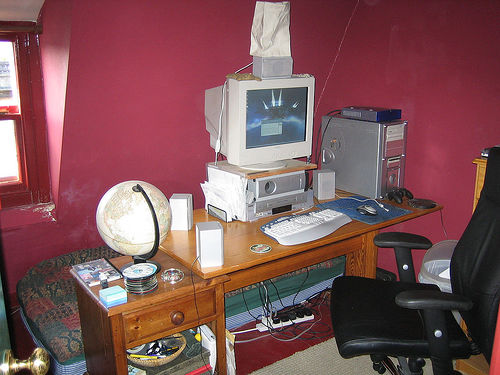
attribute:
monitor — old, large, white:
[229, 76, 315, 164]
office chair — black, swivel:
[327, 146, 484, 373]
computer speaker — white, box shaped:
[194, 220, 224, 270]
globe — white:
[94, 180, 172, 254]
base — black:
[123, 253, 160, 272]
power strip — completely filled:
[256, 303, 316, 329]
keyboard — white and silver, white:
[263, 205, 353, 247]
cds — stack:
[123, 261, 161, 294]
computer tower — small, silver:
[317, 109, 408, 197]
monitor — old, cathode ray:
[203, 70, 317, 174]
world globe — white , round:
[92, 179, 172, 261]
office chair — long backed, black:
[321, 146, 497, 367]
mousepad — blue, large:
[311, 192, 366, 217]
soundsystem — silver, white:
[203, 162, 315, 219]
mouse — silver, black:
[358, 200, 377, 216]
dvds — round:
[119, 254, 161, 291]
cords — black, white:
[246, 283, 292, 348]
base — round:
[241, 160, 288, 172]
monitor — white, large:
[198, 77, 321, 166]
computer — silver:
[311, 100, 401, 197]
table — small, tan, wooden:
[81, 242, 223, 370]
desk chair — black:
[321, 147, 499, 369]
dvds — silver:
[122, 260, 159, 293]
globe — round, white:
[91, 172, 170, 262]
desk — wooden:
[222, 213, 266, 260]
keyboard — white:
[260, 207, 348, 247]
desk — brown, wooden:
[211, 208, 289, 285]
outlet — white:
[256, 315, 278, 331]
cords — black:
[244, 282, 306, 312]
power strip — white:
[254, 313, 284, 331]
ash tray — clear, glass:
[162, 263, 184, 283]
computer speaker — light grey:
[250, 55, 299, 81]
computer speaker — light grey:
[193, 218, 227, 276]